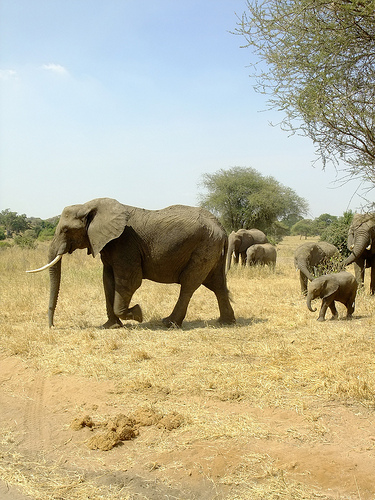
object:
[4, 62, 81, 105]
white clouds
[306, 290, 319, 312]
trunk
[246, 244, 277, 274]
elephant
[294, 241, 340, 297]
elephant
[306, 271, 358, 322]
elephant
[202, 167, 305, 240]
bush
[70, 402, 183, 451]
dunn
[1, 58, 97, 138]
cloud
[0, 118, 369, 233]
cloud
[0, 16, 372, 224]
sky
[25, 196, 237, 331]
elephant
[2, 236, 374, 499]
golden grass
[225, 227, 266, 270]
mother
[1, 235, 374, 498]
ground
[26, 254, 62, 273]
tusks